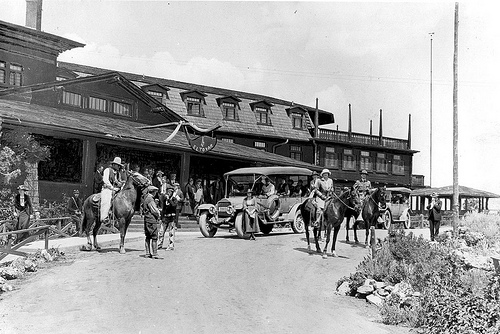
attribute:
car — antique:
[228, 156, 325, 237]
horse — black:
[285, 183, 362, 264]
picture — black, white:
[39, 63, 434, 288]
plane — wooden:
[182, 127, 225, 158]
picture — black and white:
[0, 0, 499, 332]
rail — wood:
[2, 222, 49, 258]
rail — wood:
[34, 215, 76, 239]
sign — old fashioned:
[131, 119, 223, 158]